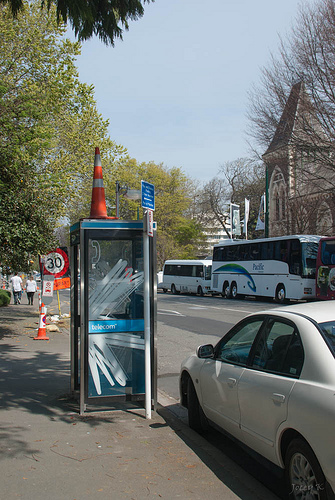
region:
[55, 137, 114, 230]
Orange and white cone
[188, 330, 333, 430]
Four door white car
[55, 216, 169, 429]
Blue telephone booth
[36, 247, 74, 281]
Speed limit of 30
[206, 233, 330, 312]
Large bus parked on road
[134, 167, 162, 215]
Tall blue and white sign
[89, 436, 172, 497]
Leaves on pavement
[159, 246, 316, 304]
Two buses parked on side of road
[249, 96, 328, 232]
Tall steeple of building.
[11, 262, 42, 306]
A couple walking with white shirts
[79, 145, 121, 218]
safety cone on phone booth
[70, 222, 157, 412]
phone booth on sidewalk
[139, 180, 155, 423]
parking signs on pole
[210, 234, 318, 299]
white bus with logo parked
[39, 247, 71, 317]
speed limit sign on side of road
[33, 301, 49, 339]
traffic cone on sidewalk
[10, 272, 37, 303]
people walking on sidewalk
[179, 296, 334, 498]
white car parked on street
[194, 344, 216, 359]
rear view mirror on white car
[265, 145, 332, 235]
building with gothic windows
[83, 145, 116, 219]
orange and white cone on telephone booth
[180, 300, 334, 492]
white car in the foreground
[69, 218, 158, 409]
a public telephone booth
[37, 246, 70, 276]
a speed limit sign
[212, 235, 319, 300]
a large white bus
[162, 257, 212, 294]
a small white bus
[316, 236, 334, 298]
a red bus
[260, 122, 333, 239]
a brick church building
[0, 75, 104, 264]
a large green tree in the background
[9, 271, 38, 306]
a man and a woman walking on the sidewalk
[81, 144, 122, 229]
an orange traffic cone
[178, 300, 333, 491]
a white family car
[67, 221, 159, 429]
a phone booth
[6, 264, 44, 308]
a couple walking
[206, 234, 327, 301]
a white passenger bus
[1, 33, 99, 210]
green tree leaves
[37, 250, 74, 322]
a group of traffic signs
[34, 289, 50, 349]
orange traffic cones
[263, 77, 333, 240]
a brown church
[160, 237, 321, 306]
two white buses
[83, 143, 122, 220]
a traffic cone is on the roof of the telephone booth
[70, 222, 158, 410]
a telephone booth with blue and white on the outside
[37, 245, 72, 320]
a traffic sign on the side of the road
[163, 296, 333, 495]
a white car parked on the side of the road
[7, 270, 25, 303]
a man walking on the sidewalk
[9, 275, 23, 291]
the man is wearing a white tee shirt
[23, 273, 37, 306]
a woman walking down the sidewalk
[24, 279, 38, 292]
the woman is wearing a white tee shirt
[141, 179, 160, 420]
road signs on a side of the road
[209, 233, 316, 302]
a bus parked on the side of the road